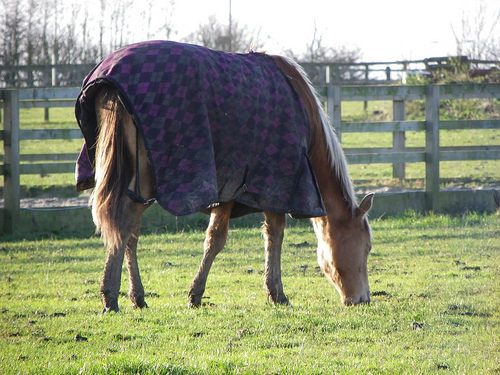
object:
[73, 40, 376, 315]
horse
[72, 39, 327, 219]
blanket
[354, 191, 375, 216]
ear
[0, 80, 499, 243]
fence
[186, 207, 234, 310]
leg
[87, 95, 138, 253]
tail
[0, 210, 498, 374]
grass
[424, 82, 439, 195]
post